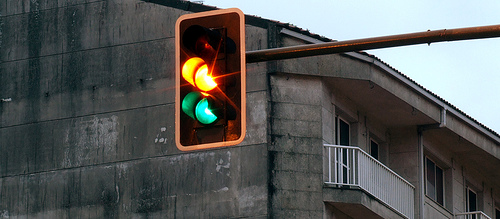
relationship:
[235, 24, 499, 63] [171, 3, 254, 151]
pole holding signal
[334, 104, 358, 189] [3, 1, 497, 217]
doors to balconies in building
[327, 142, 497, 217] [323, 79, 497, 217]
railings on balconies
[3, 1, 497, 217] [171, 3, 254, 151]
building behind signal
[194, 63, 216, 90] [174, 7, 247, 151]
light on signal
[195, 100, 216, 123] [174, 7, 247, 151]
light on signal